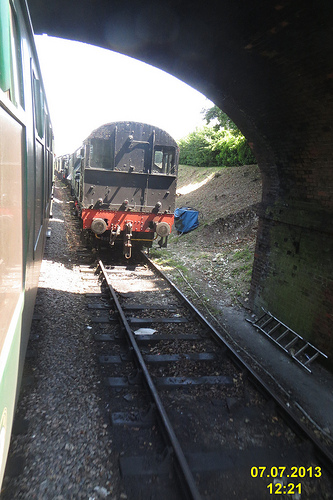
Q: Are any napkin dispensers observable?
A: No, there are no napkin dispensers.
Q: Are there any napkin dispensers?
A: No, there are no napkin dispensers.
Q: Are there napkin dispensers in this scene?
A: No, there are no napkin dispensers.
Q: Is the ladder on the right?
A: Yes, the ladder is on the right of the image.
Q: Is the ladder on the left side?
A: No, the ladder is on the right of the image.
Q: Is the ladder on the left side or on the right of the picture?
A: The ladder is on the right of the image.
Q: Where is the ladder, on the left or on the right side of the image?
A: The ladder is on the right of the image.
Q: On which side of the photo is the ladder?
A: The ladder is on the right of the image.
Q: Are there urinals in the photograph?
A: No, there are no urinals.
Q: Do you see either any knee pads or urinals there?
A: No, there are no urinals or knee pads.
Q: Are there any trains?
A: Yes, there is a train.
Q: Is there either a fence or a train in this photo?
A: Yes, there is a train.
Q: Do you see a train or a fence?
A: Yes, there is a train.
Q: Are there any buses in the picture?
A: No, there are no buses.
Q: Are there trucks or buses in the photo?
A: No, there are no buses or trucks.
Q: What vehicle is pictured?
A: The vehicle is a train.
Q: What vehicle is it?
A: The vehicle is a train.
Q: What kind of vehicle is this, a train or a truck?
A: This is a train.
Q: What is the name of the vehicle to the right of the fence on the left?
A: The vehicle is a train.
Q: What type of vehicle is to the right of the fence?
A: The vehicle is a train.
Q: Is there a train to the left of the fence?
A: No, the train is to the right of the fence.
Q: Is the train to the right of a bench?
A: No, the train is to the right of a fence.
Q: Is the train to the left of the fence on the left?
A: No, the train is to the right of the fence.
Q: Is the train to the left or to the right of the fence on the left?
A: The train is to the right of the fence.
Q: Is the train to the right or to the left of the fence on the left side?
A: The train is to the right of the fence.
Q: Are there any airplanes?
A: No, there are no airplanes.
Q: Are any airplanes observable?
A: No, there are no airplanes.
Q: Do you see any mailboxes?
A: No, there are no mailboxes.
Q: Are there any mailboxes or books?
A: No, there are no mailboxes or books.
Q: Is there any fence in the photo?
A: Yes, there is a fence.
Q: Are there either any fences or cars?
A: Yes, there is a fence.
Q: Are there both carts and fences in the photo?
A: No, there is a fence but no carts.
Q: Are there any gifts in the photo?
A: No, there are no gifts.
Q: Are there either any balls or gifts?
A: No, there are no gifts or balls.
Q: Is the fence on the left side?
A: Yes, the fence is on the left of the image.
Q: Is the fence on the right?
A: No, the fence is on the left of the image.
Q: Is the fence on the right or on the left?
A: The fence is on the left of the image.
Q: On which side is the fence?
A: The fence is on the left of the image.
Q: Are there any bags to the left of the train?
A: No, there is a fence to the left of the train.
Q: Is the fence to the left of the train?
A: Yes, the fence is to the left of the train.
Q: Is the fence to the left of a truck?
A: No, the fence is to the left of the train.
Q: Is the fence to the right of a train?
A: No, the fence is to the left of a train.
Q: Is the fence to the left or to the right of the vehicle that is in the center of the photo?
A: The fence is to the left of the train.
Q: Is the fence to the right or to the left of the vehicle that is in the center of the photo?
A: The fence is to the left of the train.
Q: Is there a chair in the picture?
A: No, there are no chairs.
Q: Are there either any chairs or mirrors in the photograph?
A: No, there are no chairs or mirrors.